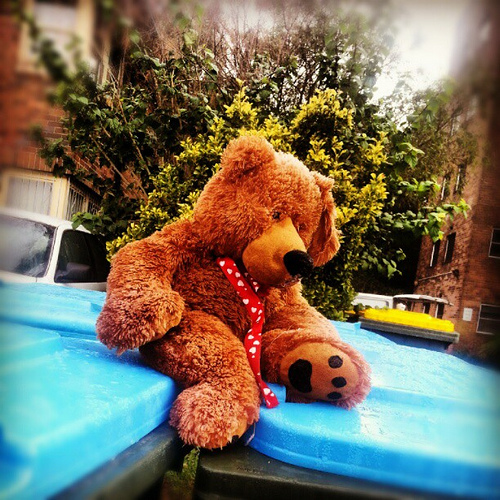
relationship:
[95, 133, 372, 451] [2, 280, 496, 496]
bear on trash cans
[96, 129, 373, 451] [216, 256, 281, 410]
bear wearing neck collar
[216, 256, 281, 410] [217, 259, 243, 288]
neck collar with hearts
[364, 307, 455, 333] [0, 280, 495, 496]
lid on garbage can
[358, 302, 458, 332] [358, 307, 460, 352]
lid on garbage can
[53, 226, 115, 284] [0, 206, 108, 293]
window on car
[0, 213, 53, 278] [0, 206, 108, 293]
window on car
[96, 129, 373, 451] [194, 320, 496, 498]
bear on bench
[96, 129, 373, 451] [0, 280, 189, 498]
bear on bench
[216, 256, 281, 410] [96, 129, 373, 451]
neck collar on bear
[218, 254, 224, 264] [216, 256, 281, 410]
heart on neck collar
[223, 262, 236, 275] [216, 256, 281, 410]
heart on neck collar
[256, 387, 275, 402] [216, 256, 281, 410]
heart on neck collar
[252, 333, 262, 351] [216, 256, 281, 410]
heart on neck collar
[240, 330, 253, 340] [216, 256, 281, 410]
heart on neck collar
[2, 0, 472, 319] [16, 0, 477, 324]
leaves on leaves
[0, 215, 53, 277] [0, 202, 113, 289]
window on car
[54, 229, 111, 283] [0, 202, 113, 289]
window on car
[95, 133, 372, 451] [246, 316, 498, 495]
bear on table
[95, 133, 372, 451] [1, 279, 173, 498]
bear on table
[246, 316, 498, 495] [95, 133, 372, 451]
table on bear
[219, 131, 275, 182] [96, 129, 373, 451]
ear attached to bear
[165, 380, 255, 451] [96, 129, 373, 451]
foot belonging to bear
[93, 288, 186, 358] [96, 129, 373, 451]
paw belonging to bear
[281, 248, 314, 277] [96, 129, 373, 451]
nose sewn on bear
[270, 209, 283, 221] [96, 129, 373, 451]
eye sewn on bear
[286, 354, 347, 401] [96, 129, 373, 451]
footprint sewn on bear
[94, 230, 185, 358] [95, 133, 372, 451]
limb attached to bear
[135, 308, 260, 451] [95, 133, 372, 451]
limb attached to bear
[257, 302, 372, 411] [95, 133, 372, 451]
limb attached to bear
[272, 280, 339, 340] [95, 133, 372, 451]
limb attached to bear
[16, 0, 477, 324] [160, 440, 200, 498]
leaves standing on ground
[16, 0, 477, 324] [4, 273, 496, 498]
leaves in ground